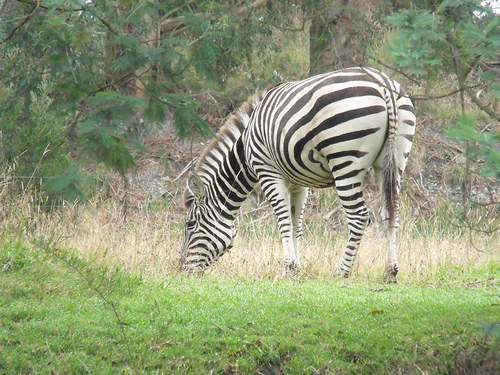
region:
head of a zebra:
[166, 199, 243, 277]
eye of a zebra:
[172, 210, 208, 231]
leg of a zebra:
[267, 191, 315, 277]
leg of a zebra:
[332, 183, 387, 295]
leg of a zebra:
[378, 188, 424, 275]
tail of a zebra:
[374, 120, 416, 222]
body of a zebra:
[271, 55, 433, 225]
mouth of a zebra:
[178, 260, 210, 284]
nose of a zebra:
[170, 258, 191, 279]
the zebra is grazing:
[182, 68, 414, 282]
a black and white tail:
[380, 148, 399, 223]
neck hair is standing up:
[196, 93, 257, 185]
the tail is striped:
[384, 90, 398, 144]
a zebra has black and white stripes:
[179, 73, 408, 268]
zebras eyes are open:
[186, 218, 199, 230]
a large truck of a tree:
[310, 0, 378, 72]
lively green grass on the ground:
[3, 276, 484, 365]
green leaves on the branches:
[385, 11, 451, 80]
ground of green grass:
[167, 275, 499, 350]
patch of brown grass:
[387, 347, 499, 372]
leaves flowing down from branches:
[1, 0, 166, 180]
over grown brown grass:
[420, 234, 472, 260]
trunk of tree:
[308, 0, 368, 60]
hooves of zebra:
[278, 251, 398, 282]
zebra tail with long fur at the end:
[381, 80, 402, 224]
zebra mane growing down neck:
[200, 90, 262, 187]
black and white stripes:
[271, 98, 328, 148]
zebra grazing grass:
[177, 67, 414, 286]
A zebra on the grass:
[164, 64, 425, 298]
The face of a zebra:
[168, 172, 239, 277]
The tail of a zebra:
[378, 81, 405, 226]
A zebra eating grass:
[167, 58, 415, 289]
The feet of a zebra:
[276, 250, 414, 281]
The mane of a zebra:
[181, 89, 267, 199]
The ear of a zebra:
[182, 171, 209, 201]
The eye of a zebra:
[183, 215, 207, 231]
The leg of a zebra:
[328, 163, 374, 275]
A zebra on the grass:
[159, 58, 414, 286]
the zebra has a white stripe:
[293, 129, 306, 140]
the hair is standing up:
[201, 131, 236, 153]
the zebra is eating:
[170, 257, 203, 285]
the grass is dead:
[147, 242, 172, 263]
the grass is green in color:
[250, 307, 285, 333]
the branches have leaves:
[83, 20, 143, 81]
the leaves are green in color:
[400, 17, 425, 52]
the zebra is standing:
[248, 155, 406, 300]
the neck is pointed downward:
[185, 124, 272, 207]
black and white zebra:
[174, 65, 417, 285]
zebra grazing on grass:
[175, 65, 415, 285]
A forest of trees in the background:
[5, 25, 497, 190]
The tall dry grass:
[17, 183, 497, 288]